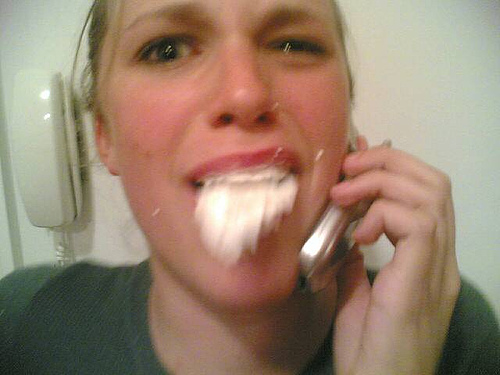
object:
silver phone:
[297, 138, 396, 295]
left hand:
[327, 144, 462, 374]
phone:
[14, 69, 87, 264]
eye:
[138, 37, 200, 73]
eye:
[267, 24, 332, 66]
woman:
[52, 5, 459, 361]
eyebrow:
[118, 5, 215, 31]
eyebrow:
[254, 3, 317, 29]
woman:
[44, 2, 408, 330]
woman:
[1, 1, 496, 373]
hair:
[71, 1, 356, 111]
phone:
[1, 66, 95, 233]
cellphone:
[297, 99, 371, 296]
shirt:
[4, 263, 494, 373]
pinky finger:
[344, 195, 441, 271]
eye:
[255, 22, 322, 94]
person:
[61, 5, 407, 355]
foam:
[192, 175, 299, 262]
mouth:
[180, 145, 303, 205]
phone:
[9, 67, 83, 264]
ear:
[87, 105, 135, 173]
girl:
[1, 0, 499, 373]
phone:
[301, 119, 397, 296]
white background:
[11, 4, 498, 319]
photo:
[8, 8, 240, 369]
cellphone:
[275, 116, 423, 311]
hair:
[67, 0, 348, 161]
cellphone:
[294, 122, 399, 307]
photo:
[4, 1, 497, 374]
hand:
[331, 137, 461, 373]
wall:
[4, 4, 498, 329]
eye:
[137, 39, 197, 65]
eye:
[271, 37, 327, 57]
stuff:
[207, 179, 280, 241]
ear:
[338, 69, 362, 142]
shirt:
[50, 260, 476, 371]